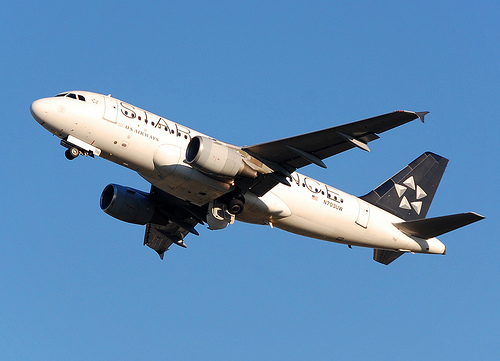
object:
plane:
[30, 89, 487, 266]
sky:
[4, 2, 499, 360]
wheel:
[228, 200, 243, 215]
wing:
[246, 111, 427, 164]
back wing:
[404, 212, 486, 241]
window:
[125, 112, 130, 118]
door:
[110, 100, 120, 117]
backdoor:
[361, 205, 373, 219]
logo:
[122, 101, 197, 140]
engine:
[187, 136, 252, 183]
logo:
[392, 175, 427, 213]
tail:
[368, 152, 449, 221]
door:
[362, 203, 371, 216]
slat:
[341, 131, 376, 155]